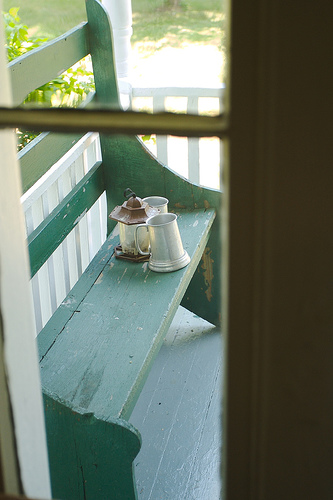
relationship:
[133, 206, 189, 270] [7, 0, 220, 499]
cup on bench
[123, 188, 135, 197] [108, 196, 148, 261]
hook on lantern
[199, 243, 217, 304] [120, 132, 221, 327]
peeling off leg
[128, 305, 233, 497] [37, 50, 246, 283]
deck of deck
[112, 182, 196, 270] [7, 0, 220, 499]
objects sitting on bench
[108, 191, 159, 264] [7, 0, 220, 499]
feeder on bench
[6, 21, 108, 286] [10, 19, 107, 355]
back of bench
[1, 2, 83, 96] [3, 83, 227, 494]
bushes behind deck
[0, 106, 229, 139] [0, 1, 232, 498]
window trim on window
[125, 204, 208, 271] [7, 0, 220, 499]
cup on bench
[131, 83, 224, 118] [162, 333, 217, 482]
railiing along deck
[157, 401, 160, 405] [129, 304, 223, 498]
speck on deck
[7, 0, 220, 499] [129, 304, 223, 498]
bench on deck